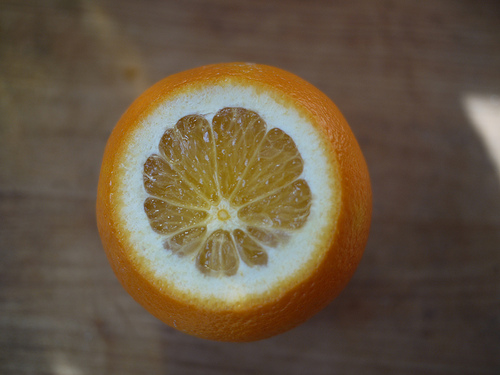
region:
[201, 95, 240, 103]
The inner white skin of an orange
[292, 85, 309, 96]
The outer skin of an orange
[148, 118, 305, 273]
The top of an orange cut off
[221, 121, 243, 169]
The inside of an orange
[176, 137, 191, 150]
Light reflecting on orange inside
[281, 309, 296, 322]
Shadow cast on outer skin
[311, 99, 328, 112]
Light reflecting on outer skin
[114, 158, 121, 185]
Lapping of outer and inner skin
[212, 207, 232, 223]
Inner core of orange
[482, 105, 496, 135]
Reflection of light on surface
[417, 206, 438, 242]
part of a table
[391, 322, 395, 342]
side of a table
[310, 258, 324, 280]
part of an apple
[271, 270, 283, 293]
part of an orange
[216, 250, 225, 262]
side of an orange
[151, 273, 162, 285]
edge of an orange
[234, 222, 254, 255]
side of an orange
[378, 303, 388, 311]
part of a surface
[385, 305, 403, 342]
edge of a surface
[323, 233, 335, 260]
side of an orange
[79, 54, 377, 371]
a slice of orange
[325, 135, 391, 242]
orange's skin is textured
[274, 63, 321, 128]
orange's skin is textured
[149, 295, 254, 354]
orange's skin is textured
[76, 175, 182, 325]
orange's skin is textured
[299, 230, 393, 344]
orange's skin is textured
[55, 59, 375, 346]
piece of an orange on table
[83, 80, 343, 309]
part of an orange sliced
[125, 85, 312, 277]
white rind of the orange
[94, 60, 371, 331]
orange rind of the orange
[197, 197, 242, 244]
white center of the orange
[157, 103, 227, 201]
fruit of orange inside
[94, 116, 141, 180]
two different shades of orange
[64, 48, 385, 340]
orange cut in half on table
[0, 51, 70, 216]
wooden table by orange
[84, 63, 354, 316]
perfectly sliced orange piece on table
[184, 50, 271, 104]
orange's skin is textured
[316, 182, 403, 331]
orange's skin is textured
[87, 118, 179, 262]
orange's skin is textured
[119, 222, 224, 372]
orange's skin is textured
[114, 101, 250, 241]
the orange has pulp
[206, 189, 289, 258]
the orange has pulp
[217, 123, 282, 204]
the orange has pulp